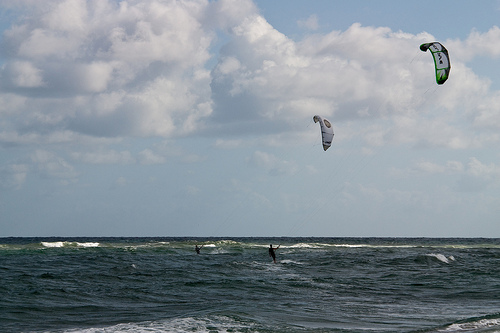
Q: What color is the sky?
A: Blue.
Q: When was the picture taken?
A: Daytime.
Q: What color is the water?
A: Blue.